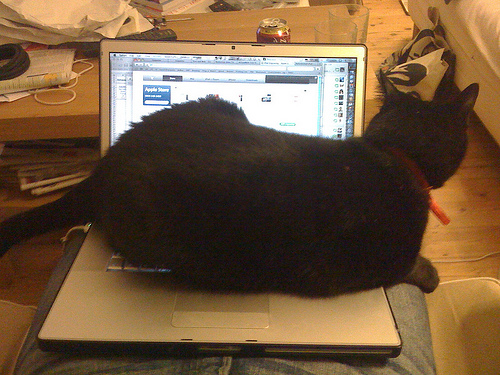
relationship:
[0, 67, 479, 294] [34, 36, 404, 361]
cat on laptop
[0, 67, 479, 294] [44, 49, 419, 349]
cat on top of laptop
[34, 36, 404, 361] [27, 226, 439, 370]
laptop open on lap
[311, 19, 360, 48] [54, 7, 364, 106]
glass sitting on table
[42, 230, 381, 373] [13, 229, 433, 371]
man wearing jeans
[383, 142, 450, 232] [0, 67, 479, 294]
collar on cat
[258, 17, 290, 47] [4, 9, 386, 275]
soda can on table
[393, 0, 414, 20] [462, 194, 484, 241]
remote on floor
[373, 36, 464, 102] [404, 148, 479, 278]
pillow on floor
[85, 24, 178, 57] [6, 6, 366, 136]
remote on table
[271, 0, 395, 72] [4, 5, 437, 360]
glass on table